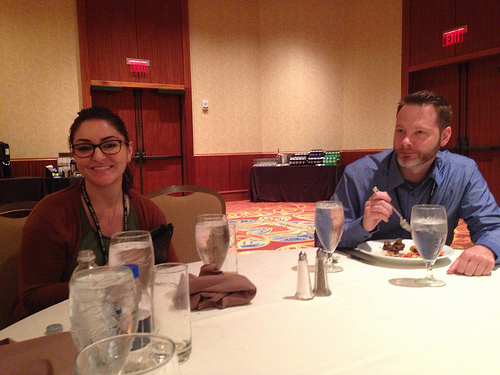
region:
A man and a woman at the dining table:
[15, 48, 491, 337]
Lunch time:
[21, 25, 495, 321]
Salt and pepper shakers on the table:
[288, 222, 358, 318]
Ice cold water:
[60, 217, 262, 323]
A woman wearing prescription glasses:
[48, 106, 231, 281]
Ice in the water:
[54, 246, 142, 369]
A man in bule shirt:
[313, 96, 492, 281]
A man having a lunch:
[291, 40, 489, 291]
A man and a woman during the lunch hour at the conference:
[11, 7, 498, 326]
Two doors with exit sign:
[61, 33, 498, 201]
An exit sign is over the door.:
[430, 19, 482, 53]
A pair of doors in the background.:
[398, 52, 499, 202]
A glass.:
[403, 195, 452, 294]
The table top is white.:
[283, 327, 446, 374]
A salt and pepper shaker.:
[286, 235, 354, 307]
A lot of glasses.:
[65, 222, 205, 370]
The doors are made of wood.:
[400, 54, 499, 204]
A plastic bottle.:
[108, 258, 160, 356]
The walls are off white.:
[231, 47, 306, 122]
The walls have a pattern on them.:
[233, 48, 300, 118]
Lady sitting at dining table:
[12, 106, 173, 308]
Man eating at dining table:
[322, 87, 497, 272]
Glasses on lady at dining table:
[65, 135, 125, 155]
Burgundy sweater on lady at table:
[11, 185, 176, 310]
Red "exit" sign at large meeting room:
[122, 51, 153, 71]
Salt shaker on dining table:
[291, 245, 308, 300]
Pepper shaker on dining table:
[311, 241, 328, 296]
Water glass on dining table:
[405, 200, 450, 290]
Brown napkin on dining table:
[170, 270, 257, 315]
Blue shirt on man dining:
[327, 148, 498, 255]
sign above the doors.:
[127, 57, 153, 72]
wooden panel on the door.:
[148, 115, 166, 145]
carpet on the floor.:
[246, 206, 290, 236]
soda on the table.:
[293, 150, 335, 162]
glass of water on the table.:
[408, 220, 442, 277]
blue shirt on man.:
[441, 166, 471, 211]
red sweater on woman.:
[35, 201, 59, 271]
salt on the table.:
[292, 251, 312, 295]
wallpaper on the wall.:
[35, 43, 71, 123]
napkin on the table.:
[197, 273, 247, 299]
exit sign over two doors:
[401, 23, 499, 210]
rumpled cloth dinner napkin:
[172, 260, 259, 312]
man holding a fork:
[313, 88, 498, 278]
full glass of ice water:
[66, 262, 141, 374]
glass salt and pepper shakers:
[293, 245, 333, 301]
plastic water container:
[108, 261, 152, 374]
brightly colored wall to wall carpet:
[223, 198, 499, 258]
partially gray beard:
[392, 130, 442, 168]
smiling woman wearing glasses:
[19, 103, 181, 318]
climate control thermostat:
[200, 97, 210, 115]